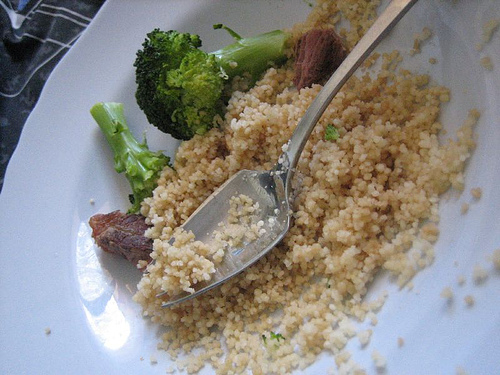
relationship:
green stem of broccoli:
[91, 97, 173, 203] [130, 27, 263, 139]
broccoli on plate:
[135, 23, 290, 141] [18, 195, 60, 309]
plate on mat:
[1, 2, 498, 373] [0, 0, 106, 197]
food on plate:
[88, 209, 153, 271] [1, 2, 498, 373]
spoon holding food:
[110, 0, 428, 297] [80, 28, 465, 347]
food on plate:
[80, 28, 465, 347] [1, 2, 498, 373]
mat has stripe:
[0, 0, 113, 191] [0, 28, 84, 103]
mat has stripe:
[0, 0, 113, 191] [12, 31, 74, 50]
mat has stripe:
[0, 0, 113, 191] [26, 10, 90, 29]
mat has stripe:
[0, 0, 113, 191] [36, 0, 94, 21]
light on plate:
[55, 249, 116, 347] [1, 2, 498, 373]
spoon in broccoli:
[144, 0, 419, 308] [135, 23, 290, 141]